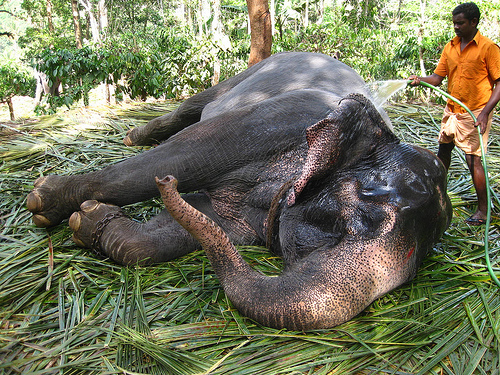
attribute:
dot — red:
[399, 245, 417, 265]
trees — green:
[42, 5, 218, 98]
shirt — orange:
[405, 29, 483, 111]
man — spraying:
[418, 1, 488, 227]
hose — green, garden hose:
[404, 71, 499, 288]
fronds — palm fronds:
[0, 100, 500, 370]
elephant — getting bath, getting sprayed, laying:
[27, 50, 457, 327]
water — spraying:
[345, 73, 420, 114]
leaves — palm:
[0, 91, 500, 371]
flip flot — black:
[454, 188, 486, 242]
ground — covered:
[32, 201, 404, 372]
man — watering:
[407, 6, 497, 140]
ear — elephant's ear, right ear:
[259, 70, 402, 247]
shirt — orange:
[431, 30, 483, 112]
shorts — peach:
[429, 105, 483, 158]